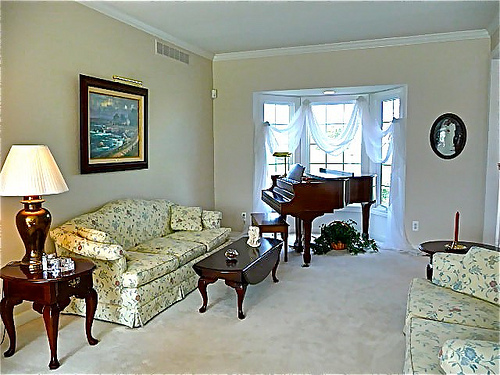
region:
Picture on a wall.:
[420, 99, 470, 173]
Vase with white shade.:
[7, 141, 63, 258]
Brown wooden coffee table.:
[186, 209, 278, 322]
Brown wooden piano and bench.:
[273, 157, 379, 272]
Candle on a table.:
[418, 203, 470, 262]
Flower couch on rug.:
[83, 173, 213, 338]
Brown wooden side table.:
[8, 260, 93, 372]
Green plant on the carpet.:
[318, 212, 380, 292]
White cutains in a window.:
[235, 75, 412, 169]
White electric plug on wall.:
[402, 214, 427, 256]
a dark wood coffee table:
[192, 231, 291, 320]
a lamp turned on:
[0, 137, 70, 268]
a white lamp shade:
[0, 141, 77, 203]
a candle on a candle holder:
[444, 211, 465, 251]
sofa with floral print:
[48, 192, 233, 333]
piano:
[260, 160, 387, 264]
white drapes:
[250, 92, 415, 244]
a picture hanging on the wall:
[78, 73, 153, 174]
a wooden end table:
[0, 255, 102, 372]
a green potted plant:
[310, 219, 385, 261]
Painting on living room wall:
[76, 66, 158, 178]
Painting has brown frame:
[74, 69, 162, 179]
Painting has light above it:
[100, 62, 163, 106]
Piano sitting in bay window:
[257, 149, 395, 262]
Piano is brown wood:
[266, 158, 385, 265]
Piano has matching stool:
[246, 200, 296, 270]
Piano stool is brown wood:
[248, 200, 293, 268]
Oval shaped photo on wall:
[423, 102, 468, 167]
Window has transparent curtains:
[243, 79, 409, 253]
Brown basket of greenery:
[306, 212, 381, 267]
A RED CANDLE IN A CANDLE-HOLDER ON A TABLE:
[442, 206, 471, 256]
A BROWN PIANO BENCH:
[244, 207, 297, 270]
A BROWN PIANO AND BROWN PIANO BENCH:
[247, 147, 387, 270]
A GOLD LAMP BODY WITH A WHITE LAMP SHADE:
[0, 137, 80, 281]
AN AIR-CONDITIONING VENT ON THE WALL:
[150, 35, 196, 72]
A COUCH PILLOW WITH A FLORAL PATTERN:
[167, 200, 207, 233]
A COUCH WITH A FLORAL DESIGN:
[39, 190, 244, 330]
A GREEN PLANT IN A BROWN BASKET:
[299, 216, 384, 263]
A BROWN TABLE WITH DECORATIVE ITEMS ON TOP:
[189, 222, 292, 324]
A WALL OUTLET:
[409, 218, 421, 233]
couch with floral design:
[50, 194, 228, 324]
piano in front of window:
[261, 162, 378, 266]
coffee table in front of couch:
[180, 227, 294, 322]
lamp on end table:
[6, 134, 71, 279]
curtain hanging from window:
[263, 91, 408, 161]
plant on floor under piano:
[302, 213, 383, 262]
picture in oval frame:
[419, 104, 474, 166]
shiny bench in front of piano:
[248, 207, 291, 239]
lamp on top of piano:
[267, 145, 297, 175]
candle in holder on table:
[443, 201, 469, 253]